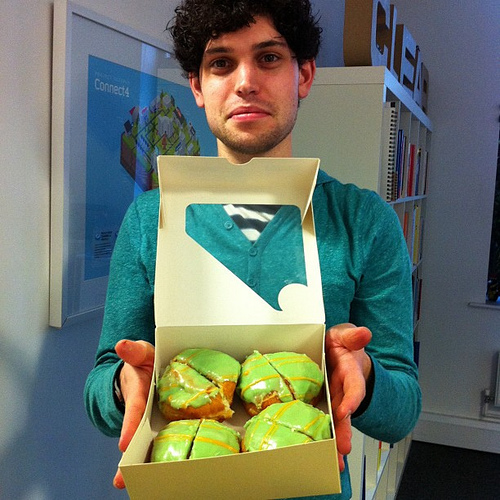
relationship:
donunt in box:
[153, 415, 237, 463] [116, 152, 343, 495]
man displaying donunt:
[85, 3, 421, 500] [240, 351, 320, 404]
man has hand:
[85, 3, 421, 500] [102, 332, 157, 489]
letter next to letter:
[413, 51, 424, 104] [419, 66, 432, 115]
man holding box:
[85, 3, 421, 500] [116, 152, 343, 495]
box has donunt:
[116, 152, 343, 495] [159, 345, 234, 416]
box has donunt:
[116, 152, 343, 495] [240, 351, 320, 404]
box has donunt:
[116, 152, 343, 495] [153, 415, 237, 463]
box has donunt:
[116, 152, 343, 495] [239, 397, 328, 455]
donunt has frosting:
[159, 345, 234, 416] [163, 352, 238, 402]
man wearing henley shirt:
[85, 3, 421, 500] [81, 173, 420, 500]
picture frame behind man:
[50, 4, 230, 331] [85, 3, 421, 500]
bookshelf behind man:
[265, 65, 423, 498] [85, 3, 421, 500]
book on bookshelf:
[393, 129, 405, 192] [265, 65, 423, 498]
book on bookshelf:
[406, 139, 415, 196] [265, 65, 423, 498]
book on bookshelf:
[384, 102, 397, 196] [265, 65, 423, 498]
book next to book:
[406, 211, 414, 264] [411, 205, 424, 263]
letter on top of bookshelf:
[344, 1, 394, 70] [265, 65, 423, 498]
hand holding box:
[102, 332, 157, 489] [116, 152, 343, 495]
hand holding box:
[327, 318, 370, 466] [116, 152, 343, 495]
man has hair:
[85, 3, 421, 500] [171, 2, 322, 67]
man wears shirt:
[85, 3, 421, 500] [224, 201, 281, 245]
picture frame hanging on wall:
[50, 4, 230, 331] [3, 2, 219, 500]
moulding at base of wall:
[411, 411, 493, 452] [308, 1, 499, 451]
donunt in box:
[159, 345, 234, 416] [116, 152, 343, 495]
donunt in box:
[240, 351, 320, 404] [116, 152, 343, 495]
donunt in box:
[239, 397, 328, 455] [116, 152, 343, 495]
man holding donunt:
[85, 3, 421, 500] [240, 351, 320, 404]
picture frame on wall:
[50, 4, 230, 331] [3, 2, 219, 500]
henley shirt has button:
[81, 173, 420, 500] [247, 274, 256, 286]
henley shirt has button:
[81, 173, 420, 500] [248, 245, 257, 256]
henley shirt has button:
[81, 173, 420, 500] [223, 220, 234, 229]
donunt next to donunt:
[159, 345, 234, 416] [240, 351, 320, 404]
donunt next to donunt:
[153, 415, 237, 463] [239, 397, 328, 455]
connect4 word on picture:
[92, 76, 134, 104] [69, 16, 239, 308]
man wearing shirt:
[85, 3, 421, 500] [224, 201, 281, 245]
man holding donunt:
[85, 3, 421, 500] [159, 345, 234, 416]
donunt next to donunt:
[240, 351, 320, 404] [239, 397, 328, 455]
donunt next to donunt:
[239, 397, 328, 455] [153, 415, 237, 463]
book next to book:
[406, 139, 415, 196] [406, 211, 414, 264]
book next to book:
[411, 205, 424, 263] [406, 211, 414, 264]